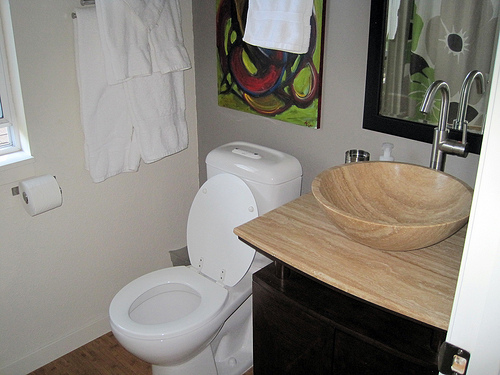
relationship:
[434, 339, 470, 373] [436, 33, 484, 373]
door latch mounted on door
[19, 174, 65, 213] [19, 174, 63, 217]
roll of roll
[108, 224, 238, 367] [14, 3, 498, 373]
toilet in bathroom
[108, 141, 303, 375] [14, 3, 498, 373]
toilet in bathroom